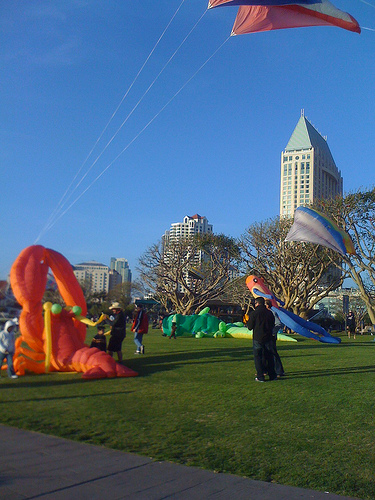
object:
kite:
[205, 1, 364, 40]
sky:
[1, 1, 374, 199]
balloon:
[10, 244, 139, 379]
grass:
[362, 480, 375, 500]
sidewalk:
[0, 419, 352, 498]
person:
[101, 300, 124, 362]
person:
[90, 324, 107, 349]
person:
[1, 319, 19, 380]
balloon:
[283, 205, 348, 258]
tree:
[134, 229, 241, 320]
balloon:
[219, 320, 226, 331]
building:
[279, 107, 344, 323]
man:
[243, 296, 276, 382]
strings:
[120, 98, 172, 156]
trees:
[323, 190, 374, 333]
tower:
[281, 107, 330, 151]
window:
[283, 156, 287, 161]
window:
[289, 155, 293, 162]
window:
[302, 155, 306, 159]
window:
[307, 153, 310, 159]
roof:
[192, 214, 202, 218]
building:
[159, 214, 214, 301]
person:
[132, 300, 148, 357]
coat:
[130, 309, 149, 334]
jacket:
[0, 320, 15, 356]